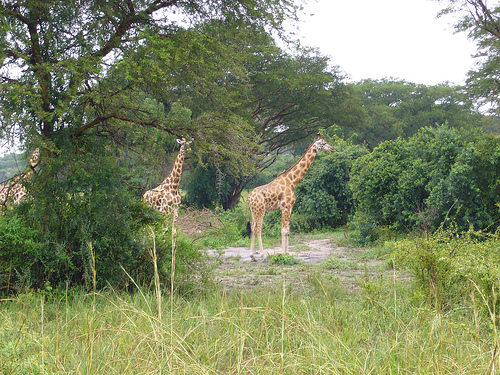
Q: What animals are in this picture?
A: Giraffes.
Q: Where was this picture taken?
A: In the wild.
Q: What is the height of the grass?
A: Tall.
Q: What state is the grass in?
A: Overgrown.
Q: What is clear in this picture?
A: The sky.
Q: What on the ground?
A: Grass.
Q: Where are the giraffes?
A: In the wild.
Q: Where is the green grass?
A: Near the giraffes.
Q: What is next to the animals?
A: Trees.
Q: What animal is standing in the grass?
A: Giraffes.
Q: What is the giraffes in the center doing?
A: Standing.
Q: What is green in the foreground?
A: Tall grass.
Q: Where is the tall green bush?
A: On the right in the center.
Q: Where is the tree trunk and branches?
A: Behind the giraffes.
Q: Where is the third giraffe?
A: On the left behind bushes.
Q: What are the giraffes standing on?
A: Sandy dirt.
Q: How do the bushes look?
A: Green and leafy.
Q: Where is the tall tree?
A: On the left.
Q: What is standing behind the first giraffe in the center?
A: Two giraffes.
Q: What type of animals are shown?
A: Giraffes.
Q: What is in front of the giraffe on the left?
A: Tree.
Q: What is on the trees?
A: Leaves.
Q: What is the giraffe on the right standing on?
A: Dirt.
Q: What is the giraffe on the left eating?
A: Leaves.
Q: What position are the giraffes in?
A: Standing.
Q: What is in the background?
A: Trees.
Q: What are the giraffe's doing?
A: Standing in the field.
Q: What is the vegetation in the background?
A: Trees.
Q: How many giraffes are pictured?
A: Three.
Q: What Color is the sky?
A: The sky's grayish colored.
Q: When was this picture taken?
A: Day time.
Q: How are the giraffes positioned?
A: They are in a line.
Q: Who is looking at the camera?
A: The middle giraffe.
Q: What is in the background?
A: There are trees in the background.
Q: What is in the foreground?
A: Long grass is in the foreground.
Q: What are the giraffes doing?
A: The giraffes are standing.